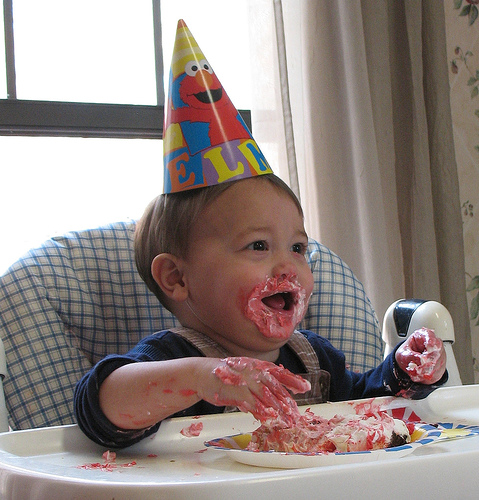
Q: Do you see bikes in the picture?
A: No, there are no bikes.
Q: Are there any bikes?
A: No, there are no bikes.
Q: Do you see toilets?
A: No, there are no toilets.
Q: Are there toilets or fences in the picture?
A: No, there are no toilets or fences.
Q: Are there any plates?
A: Yes, there is a plate.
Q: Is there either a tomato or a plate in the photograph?
A: Yes, there is a plate.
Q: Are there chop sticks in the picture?
A: No, there are no chop sticks.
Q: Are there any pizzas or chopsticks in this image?
A: No, there are no chopsticks or pizzas.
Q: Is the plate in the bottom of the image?
A: Yes, the plate is in the bottom of the image.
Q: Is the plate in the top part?
A: No, the plate is in the bottom of the image.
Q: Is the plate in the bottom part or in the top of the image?
A: The plate is in the bottom of the image.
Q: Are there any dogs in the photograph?
A: No, there are no dogs.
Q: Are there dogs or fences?
A: No, there are no dogs or fences.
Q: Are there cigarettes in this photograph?
A: No, there are no cigarettes.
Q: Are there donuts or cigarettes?
A: No, there are no cigarettes or donuts.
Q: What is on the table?
A: The frosting is on the table.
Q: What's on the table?
A: The frosting is on the table.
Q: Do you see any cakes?
A: Yes, there is a cake.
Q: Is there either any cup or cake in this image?
A: Yes, there is a cake.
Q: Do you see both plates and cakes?
A: Yes, there are both a cake and a plate.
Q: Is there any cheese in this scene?
A: No, there is no cheese.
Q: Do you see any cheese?
A: No, there is no cheese.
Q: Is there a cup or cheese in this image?
A: No, there are no cheese or cups.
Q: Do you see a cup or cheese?
A: No, there are no cheese or cups.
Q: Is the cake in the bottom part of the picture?
A: Yes, the cake is in the bottom of the image.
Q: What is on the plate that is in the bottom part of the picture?
A: The cake is on the plate.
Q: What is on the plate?
A: The cake is on the plate.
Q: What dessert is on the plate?
A: The dessert is a cake.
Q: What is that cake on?
A: The cake is on the plate.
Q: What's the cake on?
A: The cake is on the plate.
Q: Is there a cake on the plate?
A: Yes, there is a cake on the plate.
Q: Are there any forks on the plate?
A: No, there is a cake on the plate.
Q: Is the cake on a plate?
A: Yes, the cake is on a plate.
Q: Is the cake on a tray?
A: No, the cake is on a plate.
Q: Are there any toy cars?
A: No, there are no toy cars.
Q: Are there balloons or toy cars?
A: No, there are no toy cars or balloons.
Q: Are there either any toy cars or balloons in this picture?
A: No, there are no toy cars or balloons.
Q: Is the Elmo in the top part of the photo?
A: Yes, the Elmo is in the top of the image.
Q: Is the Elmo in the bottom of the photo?
A: No, the Elmo is in the top of the image.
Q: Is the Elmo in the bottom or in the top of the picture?
A: The Elmo is in the top of the image.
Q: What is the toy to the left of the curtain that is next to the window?
A: The toy is an Elmo.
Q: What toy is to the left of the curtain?
A: The toy is an Elmo.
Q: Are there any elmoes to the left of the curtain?
A: Yes, there is an Elmo to the left of the curtain.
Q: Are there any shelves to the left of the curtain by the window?
A: No, there is an Elmo to the left of the curtain.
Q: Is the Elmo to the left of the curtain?
A: Yes, the Elmo is to the left of the curtain.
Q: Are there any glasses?
A: No, there are no glasses.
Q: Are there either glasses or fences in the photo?
A: No, there are no glasses or fences.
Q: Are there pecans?
A: No, there are no pecans.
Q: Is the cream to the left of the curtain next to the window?
A: Yes, the cream is to the left of the curtain.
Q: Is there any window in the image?
A: Yes, there is a window.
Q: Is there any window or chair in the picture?
A: Yes, there is a window.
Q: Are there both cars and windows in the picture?
A: No, there is a window but no cars.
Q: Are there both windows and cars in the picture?
A: No, there is a window but no cars.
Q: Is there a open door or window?
A: Yes, there is an open window.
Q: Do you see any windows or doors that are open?
A: Yes, the window is open.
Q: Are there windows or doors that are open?
A: Yes, the window is open.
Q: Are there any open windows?
A: Yes, there is an open window.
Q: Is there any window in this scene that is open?
A: Yes, there is a window that is open.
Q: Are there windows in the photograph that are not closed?
A: Yes, there is a open window.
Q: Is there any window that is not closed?
A: Yes, there is a open window.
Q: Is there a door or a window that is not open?
A: No, there is a window but it is open.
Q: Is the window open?
A: Yes, the window is open.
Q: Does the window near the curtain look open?
A: Yes, the window is open.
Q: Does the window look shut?
A: No, the window is open.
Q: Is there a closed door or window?
A: No, there is a window but it is open.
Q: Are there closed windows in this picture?
A: No, there is a window but it is open.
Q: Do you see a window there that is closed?
A: No, there is a window but it is open.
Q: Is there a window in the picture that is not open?
A: No, there is a window but it is open.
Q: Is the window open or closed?
A: The window is open.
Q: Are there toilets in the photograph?
A: No, there are no toilets.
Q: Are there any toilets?
A: No, there are no toilets.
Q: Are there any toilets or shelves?
A: No, there are no toilets or shelves.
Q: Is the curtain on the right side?
A: Yes, the curtain is on the right of the image.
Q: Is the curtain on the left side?
A: No, the curtain is on the right of the image.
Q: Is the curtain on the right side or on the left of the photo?
A: The curtain is on the right of the image.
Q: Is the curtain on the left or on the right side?
A: The curtain is on the right of the image.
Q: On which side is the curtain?
A: The curtain is on the right of the image.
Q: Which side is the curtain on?
A: The curtain is on the right of the image.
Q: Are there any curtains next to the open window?
A: Yes, there is a curtain next to the window.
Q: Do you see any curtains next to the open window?
A: Yes, there is a curtain next to the window.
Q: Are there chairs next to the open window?
A: No, there is a curtain next to the window.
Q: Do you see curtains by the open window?
A: Yes, there is a curtain by the window.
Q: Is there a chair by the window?
A: No, there is a curtain by the window.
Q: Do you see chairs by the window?
A: No, there is a curtain by the window.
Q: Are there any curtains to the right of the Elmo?
A: Yes, there is a curtain to the right of the Elmo.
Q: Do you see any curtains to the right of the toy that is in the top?
A: Yes, there is a curtain to the right of the Elmo.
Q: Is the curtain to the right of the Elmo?
A: Yes, the curtain is to the right of the Elmo.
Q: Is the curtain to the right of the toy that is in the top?
A: Yes, the curtain is to the right of the Elmo.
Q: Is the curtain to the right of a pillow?
A: No, the curtain is to the right of the Elmo.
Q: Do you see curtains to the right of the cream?
A: Yes, there is a curtain to the right of the cream.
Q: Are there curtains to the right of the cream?
A: Yes, there is a curtain to the right of the cream.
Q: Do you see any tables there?
A: Yes, there is a table.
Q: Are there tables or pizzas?
A: Yes, there is a table.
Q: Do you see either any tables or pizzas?
A: Yes, there is a table.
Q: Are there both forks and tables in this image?
A: No, there is a table but no forks.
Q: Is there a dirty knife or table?
A: Yes, there is a dirty table.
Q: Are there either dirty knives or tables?
A: Yes, there is a dirty table.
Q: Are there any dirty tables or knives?
A: Yes, there is a dirty table.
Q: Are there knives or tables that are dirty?
A: Yes, the table is dirty.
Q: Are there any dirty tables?
A: Yes, there is a dirty table.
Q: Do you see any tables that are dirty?
A: Yes, there is a table that is dirty.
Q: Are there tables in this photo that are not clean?
A: Yes, there is a dirty table.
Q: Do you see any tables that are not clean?
A: Yes, there is a dirty table.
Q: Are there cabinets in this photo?
A: No, there are no cabinets.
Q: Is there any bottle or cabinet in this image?
A: No, there are no cabinets or bottles.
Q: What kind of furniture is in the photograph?
A: The furniture is a table.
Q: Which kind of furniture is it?
A: The piece of furniture is a table.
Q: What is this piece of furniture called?
A: This is a table.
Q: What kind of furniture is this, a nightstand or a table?
A: This is a table.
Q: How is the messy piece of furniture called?
A: The piece of furniture is a table.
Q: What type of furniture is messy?
A: The furniture is a table.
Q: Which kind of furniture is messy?
A: The furniture is a table.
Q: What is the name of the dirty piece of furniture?
A: The piece of furniture is a table.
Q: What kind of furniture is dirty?
A: The furniture is a table.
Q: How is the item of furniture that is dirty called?
A: The piece of furniture is a table.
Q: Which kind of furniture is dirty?
A: The furniture is a table.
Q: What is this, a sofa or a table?
A: This is a table.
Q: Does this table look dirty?
A: Yes, the table is dirty.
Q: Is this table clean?
A: No, the table is dirty.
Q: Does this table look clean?
A: No, the table is dirty.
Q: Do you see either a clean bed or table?
A: No, there is a table but it is dirty.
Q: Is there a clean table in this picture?
A: No, there is a table but it is dirty.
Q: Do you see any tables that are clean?
A: No, there is a table but it is dirty.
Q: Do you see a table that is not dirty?
A: No, there is a table but it is dirty.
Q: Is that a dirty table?
A: Yes, that is a dirty table.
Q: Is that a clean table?
A: No, that is a dirty table.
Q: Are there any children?
A: Yes, there is a child.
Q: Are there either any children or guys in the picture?
A: Yes, there is a child.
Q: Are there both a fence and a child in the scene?
A: No, there is a child but no fences.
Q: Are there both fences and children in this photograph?
A: No, there is a child but no fences.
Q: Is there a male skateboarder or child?
A: Yes, there is a male child.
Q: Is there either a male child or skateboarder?
A: Yes, there is a male child.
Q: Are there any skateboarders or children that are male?
A: Yes, the child is male.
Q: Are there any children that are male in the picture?
A: Yes, there is a male child.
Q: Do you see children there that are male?
A: Yes, there is a child that is male.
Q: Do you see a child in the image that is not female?
A: Yes, there is a male child.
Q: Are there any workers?
A: No, there are no workers.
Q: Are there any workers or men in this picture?
A: No, there are no workers or men.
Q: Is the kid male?
A: Yes, the kid is male.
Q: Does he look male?
A: Yes, the kid is male.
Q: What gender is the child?
A: The child is male.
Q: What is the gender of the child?
A: The child is male.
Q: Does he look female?
A: No, the kid is male.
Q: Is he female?
A: No, the kid is male.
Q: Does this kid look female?
A: No, the kid is male.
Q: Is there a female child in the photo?
A: No, there is a child but he is male.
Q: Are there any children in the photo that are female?
A: No, there is a child but he is male.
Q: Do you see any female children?
A: No, there is a child but he is male.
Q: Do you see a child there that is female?
A: No, there is a child but he is male.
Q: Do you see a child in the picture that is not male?
A: No, there is a child but he is male.